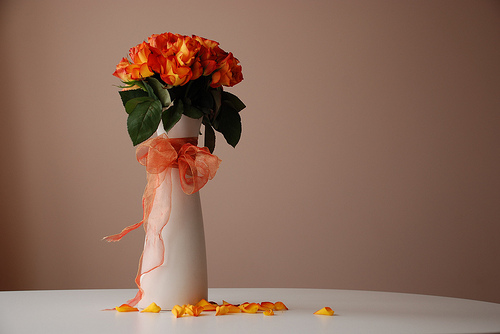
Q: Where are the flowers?
A: In the vase.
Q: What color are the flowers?
A: Orange.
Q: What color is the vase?
A: White.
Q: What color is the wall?
A: Brown.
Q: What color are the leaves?
A: Green.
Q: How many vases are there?
A: One.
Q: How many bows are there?
A: One.